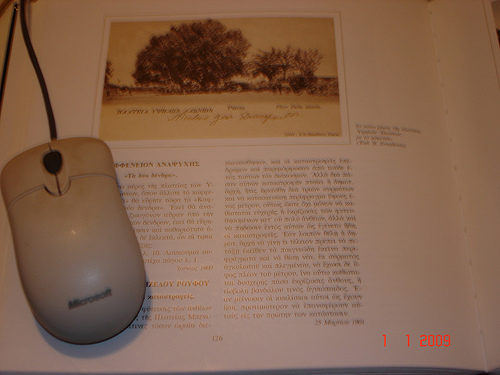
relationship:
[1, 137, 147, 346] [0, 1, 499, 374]
mouse over book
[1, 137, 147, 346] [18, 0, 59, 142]
mouse has wire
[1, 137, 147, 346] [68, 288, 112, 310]
mouse has word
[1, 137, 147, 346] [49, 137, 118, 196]
mouse has button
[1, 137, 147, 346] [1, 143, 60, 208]
mouse has button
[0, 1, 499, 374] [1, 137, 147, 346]
book under mouse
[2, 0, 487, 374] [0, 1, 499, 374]
page in book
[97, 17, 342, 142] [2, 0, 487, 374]
picture in page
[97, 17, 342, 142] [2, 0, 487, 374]
picture at top of page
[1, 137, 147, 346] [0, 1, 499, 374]
mouse on book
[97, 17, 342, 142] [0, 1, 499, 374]
picture in book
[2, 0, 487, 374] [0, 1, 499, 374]
page of book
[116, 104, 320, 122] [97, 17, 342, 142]
writing on picture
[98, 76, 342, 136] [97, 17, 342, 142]
field in picture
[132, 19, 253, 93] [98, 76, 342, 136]
tree in field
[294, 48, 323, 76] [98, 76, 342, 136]
tree in field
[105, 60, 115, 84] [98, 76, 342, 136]
tree in field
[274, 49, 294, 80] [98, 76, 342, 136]
tree in field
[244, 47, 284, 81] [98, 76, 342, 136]
tree in field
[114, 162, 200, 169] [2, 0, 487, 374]
title on page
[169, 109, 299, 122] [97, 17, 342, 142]
handwriting on picture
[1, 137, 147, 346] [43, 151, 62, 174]
mouse has scroll wheel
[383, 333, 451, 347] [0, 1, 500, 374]
date at bottom of picture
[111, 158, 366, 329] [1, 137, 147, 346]
text under mouse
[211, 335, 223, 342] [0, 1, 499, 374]
page number at bottom of book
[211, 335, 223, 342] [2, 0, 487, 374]
page number at bottom of page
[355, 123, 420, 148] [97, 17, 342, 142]
caption next to picture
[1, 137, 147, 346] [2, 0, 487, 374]
mouse on page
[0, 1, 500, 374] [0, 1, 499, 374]
picture of book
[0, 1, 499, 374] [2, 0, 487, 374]
book open to page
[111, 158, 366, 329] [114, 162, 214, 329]
text in column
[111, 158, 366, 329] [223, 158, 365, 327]
text in column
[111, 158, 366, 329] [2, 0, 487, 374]
text in page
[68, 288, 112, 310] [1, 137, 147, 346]
word on mouse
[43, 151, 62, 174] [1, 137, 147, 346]
scroll wheel of mouse